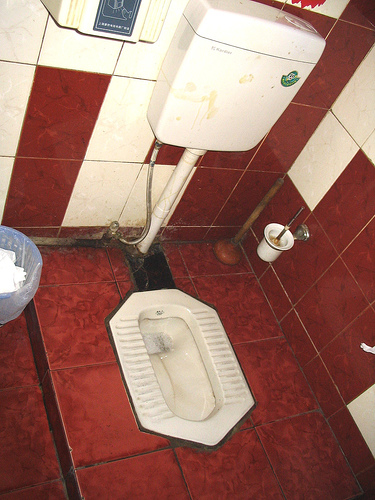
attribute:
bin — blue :
[5, 217, 64, 368]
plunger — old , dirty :
[217, 164, 307, 301]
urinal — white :
[95, 280, 285, 496]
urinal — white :
[74, 284, 279, 490]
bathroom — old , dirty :
[9, 47, 345, 466]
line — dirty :
[105, 92, 188, 280]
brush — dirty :
[258, 177, 309, 270]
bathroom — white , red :
[6, 73, 350, 478]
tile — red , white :
[289, 139, 354, 291]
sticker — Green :
[270, 38, 317, 129]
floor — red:
[261, 418, 353, 473]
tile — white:
[323, 118, 354, 162]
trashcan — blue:
[10, 234, 48, 298]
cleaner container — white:
[252, 234, 287, 265]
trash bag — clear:
[7, 293, 33, 317]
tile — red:
[15, 332, 117, 481]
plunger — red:
[216, 239, 243, 260]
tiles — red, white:
[14, 54, 112, 211]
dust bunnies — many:
[115, 222, 131, 233]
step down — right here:
[18, 324, 99, 484]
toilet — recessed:
[107, 286, 267, 463]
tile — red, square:
[35, 354, 113, 446]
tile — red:
[14, 64, 110, 160]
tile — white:
[84, 72, 154, 170]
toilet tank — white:
[145, 1, 328, 154]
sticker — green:
[276, 68, 303, 92]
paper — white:
[0, 246, 29, 293]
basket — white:
[1, 223, 48, 326]